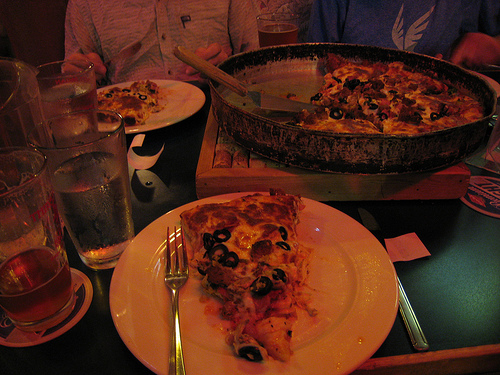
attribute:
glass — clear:
[24, 107, 151, 272]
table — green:
[10, 52, 498, 360]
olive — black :
[251, 272, 274, 294]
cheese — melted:
[180, 185, 317, 362]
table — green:
[2, 75, 496, 372]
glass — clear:
[0, 146, 78, 331]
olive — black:
[209, 225, 232, 242]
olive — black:
[251, 273, 274, 296]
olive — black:
[230, 339, 271, 363]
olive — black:
[326, 106, 345, 121]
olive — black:
[429, 110, 441, 122]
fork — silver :
[144, 210, 219, 307]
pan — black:
[196, 50, 483, 161]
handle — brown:
[169, 42, 251, 101]